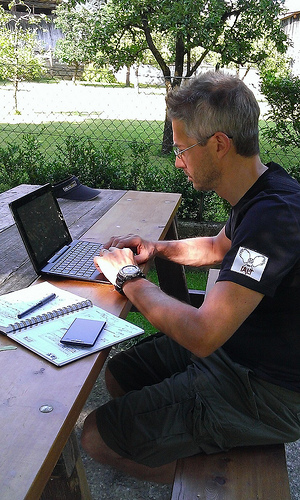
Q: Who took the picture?
A: A friend of the man sitting on the bench.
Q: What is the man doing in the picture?
A: Typing on a laptop.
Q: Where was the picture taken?
A: In a park.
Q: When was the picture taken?
A: Daytime.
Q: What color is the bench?
A: Brown.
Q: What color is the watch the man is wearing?
A: Black.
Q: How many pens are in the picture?
A: One.